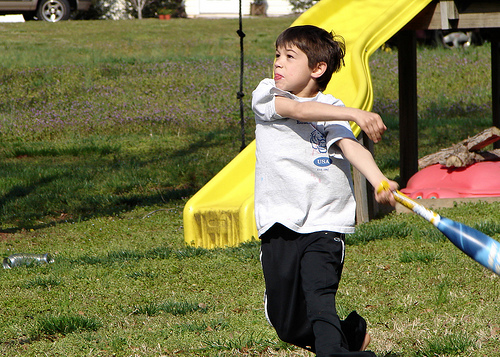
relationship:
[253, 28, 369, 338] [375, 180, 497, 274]
boy swinging bat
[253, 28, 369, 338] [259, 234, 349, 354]
boy wearing pants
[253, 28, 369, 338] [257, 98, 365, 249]
boy wearing shirt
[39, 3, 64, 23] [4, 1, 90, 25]
wheel of car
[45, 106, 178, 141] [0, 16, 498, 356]
flowers on grass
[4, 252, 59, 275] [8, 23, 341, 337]
slinky on ground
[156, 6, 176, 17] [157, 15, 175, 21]
plants in pots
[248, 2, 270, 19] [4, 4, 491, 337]
box in background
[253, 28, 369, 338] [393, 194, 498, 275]
boy swinging bat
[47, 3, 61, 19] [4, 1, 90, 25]
hubcap of car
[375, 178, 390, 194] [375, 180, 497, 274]
tip of bat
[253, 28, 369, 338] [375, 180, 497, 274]
boy holding bat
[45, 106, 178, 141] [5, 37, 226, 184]
flowers on grass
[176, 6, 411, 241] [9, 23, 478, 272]
slide in park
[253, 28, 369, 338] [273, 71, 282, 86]
boy sticking out tongue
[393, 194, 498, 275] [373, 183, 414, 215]
bat in hand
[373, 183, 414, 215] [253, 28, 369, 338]
hand of boy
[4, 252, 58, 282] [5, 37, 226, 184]
slinky in grass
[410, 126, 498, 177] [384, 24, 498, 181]
logs on sandbox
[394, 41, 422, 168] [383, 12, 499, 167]
post supports jungle gym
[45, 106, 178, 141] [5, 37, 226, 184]
flowers in grass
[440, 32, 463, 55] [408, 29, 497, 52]
mask in shadows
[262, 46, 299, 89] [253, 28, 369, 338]
face of boy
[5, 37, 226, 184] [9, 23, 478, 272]
grass in park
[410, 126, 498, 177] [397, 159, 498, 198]
logs on dome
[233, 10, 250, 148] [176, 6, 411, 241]
rope by slide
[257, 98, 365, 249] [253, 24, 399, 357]
shirt of boy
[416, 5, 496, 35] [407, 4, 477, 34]
bottom of deck